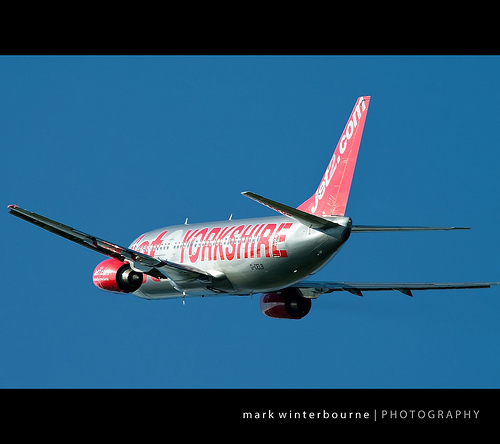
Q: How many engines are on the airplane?
A: Two.